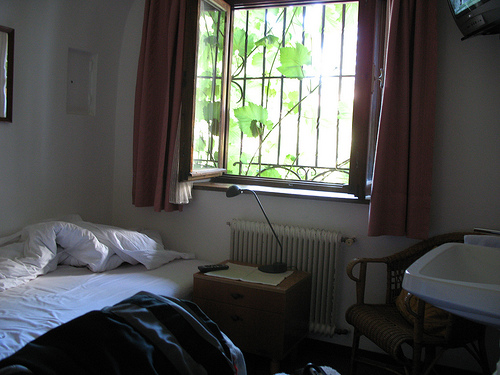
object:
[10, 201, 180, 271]
comforter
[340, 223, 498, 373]
brown chair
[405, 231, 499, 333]
sink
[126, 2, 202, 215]
curtains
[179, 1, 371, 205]
window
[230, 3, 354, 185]
bars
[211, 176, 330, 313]
lamp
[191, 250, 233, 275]
remote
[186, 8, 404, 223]
iron bar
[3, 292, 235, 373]
blanket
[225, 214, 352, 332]
radiator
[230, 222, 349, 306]
heater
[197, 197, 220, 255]
wall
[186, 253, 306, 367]
stand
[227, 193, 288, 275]
table lamp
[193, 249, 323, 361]
table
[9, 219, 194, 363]
sheet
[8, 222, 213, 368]
bed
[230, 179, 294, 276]
object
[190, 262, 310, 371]
nightstand